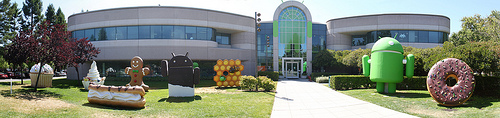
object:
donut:
[425, 57, 476, 106]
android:
[360, 33, 415, 95]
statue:
[160, 51, 201, 98]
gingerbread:
[124, 55, 151, 92]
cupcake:
[86, 83, 150, 110]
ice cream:
[81, 60, 106, 91]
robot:
[362, 33, 415, 94]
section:
[271, 0, 318, 76]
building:
[59, 0, 451, 79]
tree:
[0, 0, 103, 93]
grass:
[0, 76, 273, 118]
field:
[0, 76, 500, 118]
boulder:
[315, 75, 331, 83]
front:
[255, 40, 332, 96]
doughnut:
[425, 58, 475, 107]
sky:
[0, 0, 500, 43]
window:
[215, 31, 231, 45]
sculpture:
[361, 32, 415, 94]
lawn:
[336, 89, 499, 118]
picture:
[0, 0, 500, 118]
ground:
[0, 77, 500, 118]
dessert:
[79, 50, 244, 109]